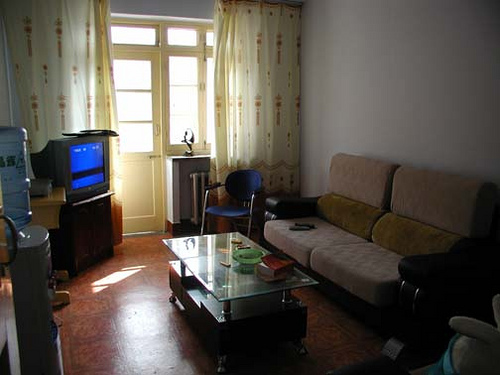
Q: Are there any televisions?
A: Yes, there is a television.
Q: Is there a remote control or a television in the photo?
A: Yes, there is a television.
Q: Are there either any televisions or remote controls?
A: Yes, there is a television.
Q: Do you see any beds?
A: No, there are no beds.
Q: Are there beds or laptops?
A: No, there are no beds or laptops.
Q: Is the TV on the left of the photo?
A: Yes, the TV is on the left of the image.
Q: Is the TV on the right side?
A: No, the TV is on the left of the image.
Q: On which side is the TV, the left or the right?
A: The TV is on the left of the image.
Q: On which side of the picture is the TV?
A: The TV is on the left of the image.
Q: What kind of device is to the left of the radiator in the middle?
A: The device is a television.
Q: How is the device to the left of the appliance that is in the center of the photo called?
A: The device is a television.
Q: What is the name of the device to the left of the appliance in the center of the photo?
A: The device is a television.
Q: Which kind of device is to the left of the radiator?
A: The device is a television.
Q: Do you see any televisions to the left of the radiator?
A: Yes, there is a television to the left of the radiator.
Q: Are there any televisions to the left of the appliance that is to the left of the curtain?
A: Yes, there is a television to the left of the radiator.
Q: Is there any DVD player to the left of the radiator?
A: No, there is a television to the left of the radiator.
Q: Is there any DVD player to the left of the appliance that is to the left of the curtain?
A: No, there is a television to the left of the radiator.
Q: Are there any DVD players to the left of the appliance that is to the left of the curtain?
A: No, there is a television to the left of the radiator.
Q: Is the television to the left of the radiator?
A: Yes, the television is to the left of the radiator.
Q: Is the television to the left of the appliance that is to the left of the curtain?
A: Yes, the television is to the left of the radiator.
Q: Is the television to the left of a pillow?
A: No, the television is to the left of the radiator.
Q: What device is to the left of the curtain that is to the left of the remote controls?
A: The device is a television.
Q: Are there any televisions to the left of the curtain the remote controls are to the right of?
A: Yes, there is a television to the left of the curtain.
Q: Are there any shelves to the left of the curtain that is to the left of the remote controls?
A: No, there is a television to the left of the curtain.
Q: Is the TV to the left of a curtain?
A: Yes, the TV is to the left of a curtain.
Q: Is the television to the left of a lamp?
A: No, the television is to the left of a curtain.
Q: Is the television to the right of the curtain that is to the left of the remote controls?
A: No, the television is to the left of the curtain.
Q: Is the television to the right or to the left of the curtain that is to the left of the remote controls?
A: The television is to the left of the curtain.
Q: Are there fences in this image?
A: No, there are no fences.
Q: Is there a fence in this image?
A: No, there are no fences.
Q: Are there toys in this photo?
A: No, there are no toys.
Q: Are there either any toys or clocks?
A: No, there are no toys or clocks.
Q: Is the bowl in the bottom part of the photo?
A: Yes, the bowl is in the bottom of the image.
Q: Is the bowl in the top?
A: No, the bowl is in the bottom of the image.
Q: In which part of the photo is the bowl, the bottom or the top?
A: The bowl is in the bottom of the image.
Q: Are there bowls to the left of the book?
A: Yes, there is a bowl to the left of the book.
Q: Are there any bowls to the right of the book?
A: No, the bowl is to the left of the book.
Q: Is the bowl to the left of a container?
A: No, the bowl is to the left of the book.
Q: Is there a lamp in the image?
A: No, there are no lamps.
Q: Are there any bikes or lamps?
A: No, there are no lamps or bikes.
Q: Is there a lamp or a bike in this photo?
A: No, there are no lamps or bikes.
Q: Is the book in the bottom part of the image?
A: Yes, the book is in the bottom of the image.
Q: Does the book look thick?
A: Yes, the book is thick.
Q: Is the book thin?
A: No, the book is thick.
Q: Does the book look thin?
A: No, the book is thick.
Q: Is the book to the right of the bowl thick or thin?
A: The book is thick.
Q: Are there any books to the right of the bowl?
A: Yes, there is a book to the right of the bowl.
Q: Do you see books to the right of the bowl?
A: Yes, there is a book to the right of the bowl.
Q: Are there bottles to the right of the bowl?
A: No, there is a book to the right of the bowl.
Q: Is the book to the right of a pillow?
A: No, the book is to the right of the bowl.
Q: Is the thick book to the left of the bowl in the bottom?
A: No, the book is to the right of the bowl.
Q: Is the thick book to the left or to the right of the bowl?
A: The book is to the right of the bowl.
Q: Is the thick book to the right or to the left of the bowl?
A: The book is to the right of the bowl.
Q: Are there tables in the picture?
A: Yes, there is a table.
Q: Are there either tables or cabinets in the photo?
A: Yes, there is a table.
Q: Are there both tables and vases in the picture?
A: No, there is a table but no vases.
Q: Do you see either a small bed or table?
A: Yes, there is a small table.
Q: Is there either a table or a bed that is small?
A: Yes, the table is small.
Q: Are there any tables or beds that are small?
A: Yes, the table is small.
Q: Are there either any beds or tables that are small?
A: Yes, the table is small.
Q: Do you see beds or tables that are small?
A: Yes, the table is small.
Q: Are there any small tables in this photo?
A: Yes, there is a small table.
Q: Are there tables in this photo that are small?
A: Yes, there is a table that is small.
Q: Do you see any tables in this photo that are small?
A: Yes, there is a table that is small.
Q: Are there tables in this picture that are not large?
A: Yes, there is a small table.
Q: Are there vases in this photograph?
A: No, there are no vases.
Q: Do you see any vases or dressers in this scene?
A: No, there are no vases or dressers.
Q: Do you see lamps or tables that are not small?
A: No, there is a table but it is small.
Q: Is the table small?
A: Yes, the table is small.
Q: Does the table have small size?
A: Yes, the table is small.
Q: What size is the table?
A: The table is small.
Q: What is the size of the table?
A: The table is small.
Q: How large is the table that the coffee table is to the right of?
A: The table is small.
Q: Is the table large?
A: No, the table is small.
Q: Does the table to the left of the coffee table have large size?
A: No, the table is small.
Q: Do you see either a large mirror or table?
A: No, there is a table but it is small.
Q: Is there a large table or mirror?
A: No, there is a table but it is small.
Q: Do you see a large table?
A: No, there is a table but it is small.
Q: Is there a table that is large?
A: No, there is a table but it is small.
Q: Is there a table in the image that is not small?
A: No, there is a table but it is small.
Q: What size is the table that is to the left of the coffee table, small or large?
A: The table is small.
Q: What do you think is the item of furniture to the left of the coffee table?
A: The piece of furniture is a table.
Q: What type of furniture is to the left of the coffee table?
A: The piece of furniture is a table.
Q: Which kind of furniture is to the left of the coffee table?
A: The piece of furniture is a table.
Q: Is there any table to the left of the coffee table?
A: Yes, there is a table to the left of the coffee table.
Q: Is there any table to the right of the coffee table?
A: No, the table is to the left of the coffee table.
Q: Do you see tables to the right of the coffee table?
A: No, the table is to the left of the coffee table.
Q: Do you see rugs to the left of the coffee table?
A: No, there is a table to the left of the coffee table.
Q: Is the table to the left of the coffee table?
A: Yes, the table is to the left of the coffee table.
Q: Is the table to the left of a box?
A: No, the table is to the left of the coffee table.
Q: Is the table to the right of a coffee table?
A: No, the table is to the left of a coffee table.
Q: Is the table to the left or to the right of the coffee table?
A: The table is to the left of the coffee table.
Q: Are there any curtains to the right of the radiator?
A: Yes, there is a curtain to the right of the radiator.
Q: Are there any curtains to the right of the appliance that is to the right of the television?
A: Yes, there is a curtain to the right of the radiator.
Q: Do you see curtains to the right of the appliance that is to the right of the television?
A: Yes, there is a curtain to the right of the radiator.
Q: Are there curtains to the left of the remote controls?
A: Yes, there is a curtain to the left of the remote controls.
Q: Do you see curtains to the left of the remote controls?
A: Yes, there is a curtain to the left of the remote controls.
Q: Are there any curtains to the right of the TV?
A: Yes, there is a curtain to the right of the TV.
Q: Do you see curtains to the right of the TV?
A: Yes, there is a curtain to the right of the TV.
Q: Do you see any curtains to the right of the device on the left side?
A: Yes, there is a curtain to the right of the TV.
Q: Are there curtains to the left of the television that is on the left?
A: No, the curtain is to the right of the television.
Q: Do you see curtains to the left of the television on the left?
A: No, the curtain is to the right of the television.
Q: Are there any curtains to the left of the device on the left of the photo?
A: No, the curtain is to the right of the television.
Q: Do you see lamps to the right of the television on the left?
A: No, there is a curtain to the right of the television.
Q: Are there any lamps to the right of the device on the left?
A: No, there is a curtain to the right of the television.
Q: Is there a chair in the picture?
A: Yes, there is a chair.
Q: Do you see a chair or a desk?
A: Yes, there is a chair.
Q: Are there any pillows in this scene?
A: No, there are no pillows.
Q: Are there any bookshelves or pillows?
A: No, there are no pillows or bookshelves.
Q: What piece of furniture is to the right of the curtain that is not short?
A: The piece of furniture is a chair.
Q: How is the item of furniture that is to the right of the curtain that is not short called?
A: The piece of furniture is a chair.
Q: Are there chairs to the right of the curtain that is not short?
A: Yes, there is a chair to the right of the curtain.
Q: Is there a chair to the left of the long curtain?
A: No, the chair is to the right of the curtain.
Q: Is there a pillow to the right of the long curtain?
A: No, there is a chair to the right of the curtain.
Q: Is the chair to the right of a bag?
A: No, the chair is to the right of the curtain.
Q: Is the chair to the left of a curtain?
A: No, the chair is to the right of a curtain.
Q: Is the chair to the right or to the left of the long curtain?
A: The chair is to the right of the curtain.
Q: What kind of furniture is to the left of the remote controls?
A: The piece of furniture is a chair.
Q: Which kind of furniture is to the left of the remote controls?
A: The piece of furniture is a chair.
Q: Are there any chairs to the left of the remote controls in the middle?
A: Yes, there is a chair to the left of the remote controls.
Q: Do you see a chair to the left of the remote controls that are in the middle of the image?
A: Yes, there is a chair to the left of the remote controls.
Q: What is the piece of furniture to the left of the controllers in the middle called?
A: The piece of furniture is a chair.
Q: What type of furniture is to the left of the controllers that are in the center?
A: The piece of furniture is a chair.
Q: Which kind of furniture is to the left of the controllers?
A: The piece of furniture is a chair.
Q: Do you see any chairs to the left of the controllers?
A: Yes, there is a chair to the left of the controllers.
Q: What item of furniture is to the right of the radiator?
A: The piece of furniture is a chair.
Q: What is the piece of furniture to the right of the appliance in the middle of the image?
A: The piece of furniture is a chair.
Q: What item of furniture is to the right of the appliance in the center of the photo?
A: The piece of furniture is a chair.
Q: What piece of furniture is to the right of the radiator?
A: The piece of furniture is a chair.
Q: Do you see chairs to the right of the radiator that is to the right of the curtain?
A: Yes, there is a chair to the right of the radiator.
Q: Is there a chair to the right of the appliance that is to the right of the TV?
A: Yes, there is a chair to the right of the radiator.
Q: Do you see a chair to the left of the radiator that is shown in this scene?
A: No, the chair is to the right of the radiator.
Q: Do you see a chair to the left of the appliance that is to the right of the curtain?
A: No, the chair is to the right of the radiator.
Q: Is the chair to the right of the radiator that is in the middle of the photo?
A: Yes, the chair is to the right of the radiator.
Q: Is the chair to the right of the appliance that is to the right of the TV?
A: Yes, the chair is to the right of the radiator.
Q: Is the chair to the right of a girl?
A: No, the chair is to the right of the radiator.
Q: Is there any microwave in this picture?
A: No, there are no microwaves.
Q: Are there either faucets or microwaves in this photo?
A: No, there are no microwaves or faucets.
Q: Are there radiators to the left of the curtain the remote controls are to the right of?
A: Yes, there is a radiator to the left of the curtain.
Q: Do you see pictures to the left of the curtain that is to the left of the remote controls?
A: No, there is a radiator to the left of the curtain.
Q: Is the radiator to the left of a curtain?
A: Yes, the radiator is to the left of a curtain.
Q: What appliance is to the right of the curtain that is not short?
A: The appliance is a radiator.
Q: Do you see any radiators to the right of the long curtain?
A: Yes, there is a radiator to the right of the curtain.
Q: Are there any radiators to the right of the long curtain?
A: Yes, there is a radiator to the right of the curtain.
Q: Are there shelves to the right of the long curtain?
A: No, there is a radiator to the right of the curtain.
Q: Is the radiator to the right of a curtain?
A: Yes, the radiator is to the right of a curtain.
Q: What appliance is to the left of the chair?
A: The appliance is a radiator.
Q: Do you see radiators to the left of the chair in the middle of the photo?
A: Yes, there is a radiator to the left of the chair.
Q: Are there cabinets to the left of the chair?
A: No, there is a radiator to the left of the chair.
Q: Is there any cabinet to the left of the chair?
A: No, there is a radiator to the left of the chair.